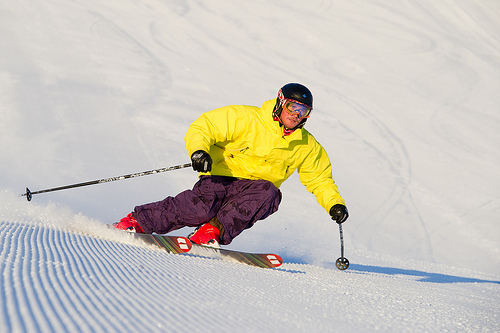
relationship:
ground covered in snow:
[5, 7, 500, 327] [6, 0, 498, 325]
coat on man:
[185, 99, 358, 212] [17, 82, 350, 270]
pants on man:
[123, 173, 279, 232] [17, 82, 350, 270]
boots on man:
[186, 223, 224, 249] [17, 82, 350, 270]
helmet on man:
[271, 81, 318, 127] [17, 82, 350, 270]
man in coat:
[17, 82, 350, 270] [185, 99, 358, 212]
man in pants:
[17, 82, 350, 270] [123, 173, 279, 232]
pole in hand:
[334, 221, 346, 270] [329, 206, 348, 225]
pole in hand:
[20, 161, 195, 202] [189, 149, 217, 174]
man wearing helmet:
[17, 82, 350, 270] [271, 81, 318, 127]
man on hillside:
[17, 82, 350, 270] [0, 1, 499, 333]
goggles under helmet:
[278, 98, 313, 119] [271, 81, 318, 127]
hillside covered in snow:
[3, 1, 499, 282] [6, 0, 498, 325]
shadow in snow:
[273, 252, 500, 289] [6, 0, 498, 325]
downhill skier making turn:
[14, 76, 361, 275] [121, 208, 292, 266]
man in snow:
[17, 76, 358, 268] [6, 0, 498, 325]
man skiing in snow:
[17, 76, 358, 268] [6, 0, 498, 325]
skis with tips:
[15, 156, 352, 270] [172, 234, 286, 271]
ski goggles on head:
[278, 92, 316, 117] [271, 82, 314, 134]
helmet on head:
[272, 83, 313, 127] [271, 82, 314, 134]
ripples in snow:
[0, 216, 500, 328] [6, 0, 498, 325]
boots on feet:
[112, 214, 231, 246] [113, 212, 224, 237]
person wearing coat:
[17, 76, 358, 268] [185, 99, 358, 212]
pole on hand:
[334, 221, 346, 270] [329, 206, 348, 225]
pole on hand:
[20, 161, 195, 202] [189, 149, 217, 174]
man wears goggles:
[17, 76, 358, 268] [278, 92, 316, 117]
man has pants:
[17, 76, 358, 268] [123, 173, 279, 232]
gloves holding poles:
[192, 148, 347, 224] [24, 159, 350, 276]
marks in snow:
[2, 211, 500, 331] [6, 0, 498, 325]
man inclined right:
[17, 76, 358, 268] [255, 0, 495, 332]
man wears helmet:
[17, 76, 358, 268] [271, 81, 318, 127]